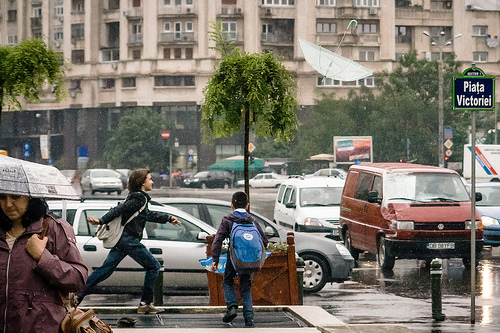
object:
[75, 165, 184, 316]
person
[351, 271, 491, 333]
street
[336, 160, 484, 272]
van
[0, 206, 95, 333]
woman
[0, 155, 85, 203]
umbrella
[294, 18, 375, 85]
umbrella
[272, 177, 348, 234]
van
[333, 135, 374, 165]
billboard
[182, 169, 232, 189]
car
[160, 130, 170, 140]
sign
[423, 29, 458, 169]
street light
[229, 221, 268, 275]
backpack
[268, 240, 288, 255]
plant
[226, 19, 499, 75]
sky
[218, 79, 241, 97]
leaves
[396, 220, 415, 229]
headlight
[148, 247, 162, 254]
handle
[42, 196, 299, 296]
car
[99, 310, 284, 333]
sidewalk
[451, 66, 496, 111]
sign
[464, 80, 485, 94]
letters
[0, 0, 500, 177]
building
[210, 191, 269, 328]
boy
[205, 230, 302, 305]
planter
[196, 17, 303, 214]
tree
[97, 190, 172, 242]
jacket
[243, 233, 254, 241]
emblem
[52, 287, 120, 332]
purse